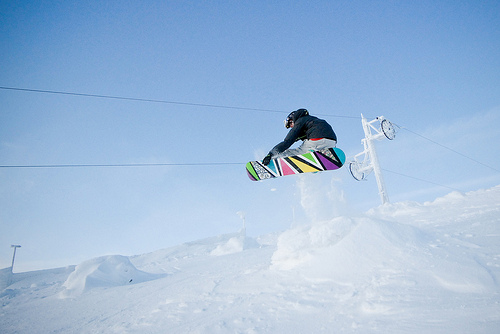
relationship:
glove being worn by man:
[261, 156, 271, 167] [243, 103, 350, 181]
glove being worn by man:
[308, 170, 318, 174] [243, 103, 350, 181]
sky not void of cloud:
[1, 1, 497, 272] [71, 156, 172, 195]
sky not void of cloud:
[1, 1, 497, 272] [344, 108, 496, 163]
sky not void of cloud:
[1, 1, 497, 272] [385, 174, 496, 203]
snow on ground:
[2, 186, 496, 331] [3, 183, 497, 331]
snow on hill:
[2, 186, 496, 331] [2, 186, 496, 331]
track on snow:
[363, 305, 390, 314] [2, 186, 496, 331]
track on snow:
[371, 292, 392, 302] [2, 186, 496, 331]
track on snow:
[373, 277, 404, 287] [2, 186, 496, 331]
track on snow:
[383, 263, 409, 275] [2, 186, 496, 331]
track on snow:
[429, 241, 443, 251] [2, 186, 496, 331]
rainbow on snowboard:
[274, 154, 341, 175] [246, 146, 345, 180]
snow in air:
[269, 186, 276, 193] [1, 0, 497, 273]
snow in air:
[293, 176, 324, 225] [1, 0, 497, 273]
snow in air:
[327, 176, 347, 219] [1, 0, 497, 273]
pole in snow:
[10, 244, 21, 275] [2, 186, 496, 331]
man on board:
[243, 103, 350, 181] [246, 149, 345, 180]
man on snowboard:
[243, 103, 350, 181] [247, 149, 344, 180]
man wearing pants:
[243, 103, 350, 181] [272, 137, 335, 158]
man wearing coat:
[243, 103, 350, 181] [264, 116, 336, 159]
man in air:
[243, 103, 350, 181] [1, 0, 497, 273]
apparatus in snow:
[348, 113, 396, 207] [2, 186, 496, 331]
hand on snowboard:
[263, 152, 272, 166] [246, 146, 345, 180]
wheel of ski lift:
[380, 117, 396, 141] [1, 86, 497, 204]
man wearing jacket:
[243, 103, 350, 180] [262, 118, 349, 158]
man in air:
[243, 103, 350, 181] [192, 67, 214, 83]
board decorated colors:
[246, 149, 345, 180] [294, 151, 335, 169]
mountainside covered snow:
[29, 190, 475, 324] [237, 228, 423, 330]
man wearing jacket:
[243, 103, 350, 181] [260, 116, 342, 173]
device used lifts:
[344, 103, 404, 194] [5, 89, 238, 191]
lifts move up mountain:
[5, 89, 238, 191] [215, 190, 463, 330]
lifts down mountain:
[5, 89, 238, 191] [215, 190, 463, 330]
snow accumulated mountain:
[274, 213, 420, 279] [227, 193, 461, 317]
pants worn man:
[293, 136, 342, 155] [255, 101, 342, 166]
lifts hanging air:
[5, 89, 238, 191] [163, 15, 273, 68]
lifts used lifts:
[5, 89, 238, 191] [5, 89, 238, 191]